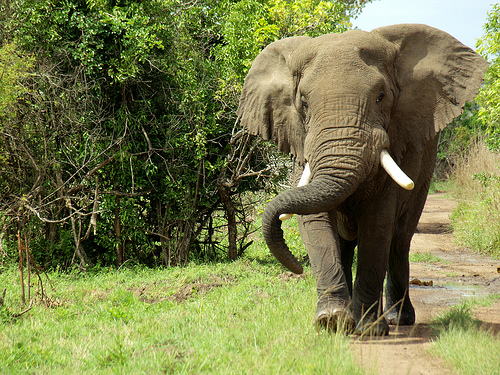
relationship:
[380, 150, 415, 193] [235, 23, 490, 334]
tusk on animal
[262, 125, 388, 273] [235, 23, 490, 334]
trunk on animal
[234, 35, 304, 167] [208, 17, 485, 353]
ear of elephant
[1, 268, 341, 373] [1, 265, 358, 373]
grass on ground